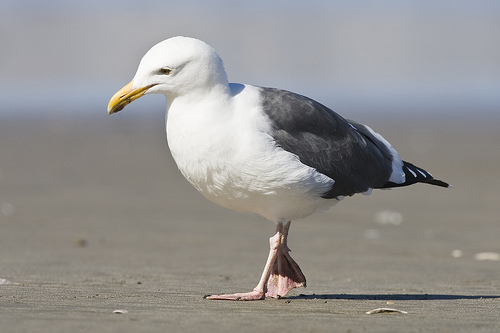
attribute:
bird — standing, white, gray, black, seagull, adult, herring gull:
[107, 36, 454, 302]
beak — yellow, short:
[107, 79, 150, 115]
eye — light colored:
[158, 68, 173, 76]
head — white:
[106, 35, 232, 116]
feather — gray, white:
[277, 128, 320, 153]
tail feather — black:
[414, 177, 453, 188]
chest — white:
[164, 102, 236, 192]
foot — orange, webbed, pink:
[203, 290, 267, 302]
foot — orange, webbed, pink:
[267, 246, 307, 300]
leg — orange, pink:
[255, 220, 282, 291]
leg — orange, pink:
[282, 220, 290, 252]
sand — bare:
[1, 113, 498, 332]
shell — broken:
[364, 308, 406, 314]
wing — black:
[261, 86, 366, 149]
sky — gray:
[1, 0, 500, 115]